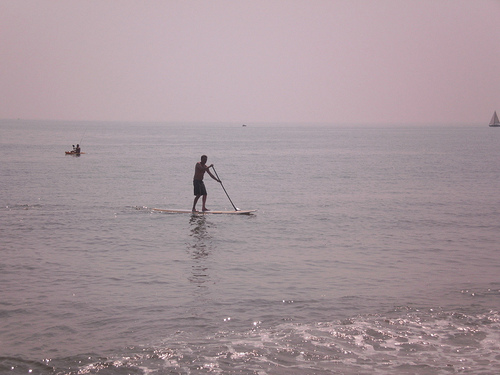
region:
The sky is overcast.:
[1, 8, 498, 124]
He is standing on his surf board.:
[162, 155, 243, 225]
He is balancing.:
[147, 153, 254, 223]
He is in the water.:
[148, 153, 268, 228]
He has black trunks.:
[133, 145, 258, 227]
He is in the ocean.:
[24, 108, 476, 373]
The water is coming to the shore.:
[67, 294, 487, 374]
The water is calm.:
[5, 113, 474, 374]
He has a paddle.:
[146, 143, 251, 220]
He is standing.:
[133, 135, 253, 227]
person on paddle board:
[146, 138, 258, 243]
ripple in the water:
[278, 330, 288, 342]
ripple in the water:
[328, 351, 350, 368]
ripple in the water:
[413, 307, 435, 323]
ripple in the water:
[168, 330, 178, 345]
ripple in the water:
[137, 323, 147, 334]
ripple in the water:
[286, 296, 300, 306]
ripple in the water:
[303, 343, 323, 355]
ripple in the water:
[436, 347, 459, 361]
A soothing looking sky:
[3, 0, 495, 126]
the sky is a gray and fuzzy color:
[0, 3, 495, 122]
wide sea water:
[7, 118, 499, 373]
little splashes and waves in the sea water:
[20, 315, 490, 374]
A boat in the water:
[486, 108, 499, 134]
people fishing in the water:
[63, 133, 88, 156]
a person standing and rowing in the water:
[146, 153, 259, 215]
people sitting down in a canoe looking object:
[60, 141, 85, 156]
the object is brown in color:
[144, 204, 256, 216]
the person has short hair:
[190, 155, 218, 213]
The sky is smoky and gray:
[50, 30, 397, 103]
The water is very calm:
[13, 227, 427, 349]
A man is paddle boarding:
[107, 140, 285, 245]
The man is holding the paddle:
[206, 158, 246, 217]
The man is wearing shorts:
[186, 175, 208, 197]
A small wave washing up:
[126, 303, 472, 368]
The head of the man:
[194, 151, 213, 168]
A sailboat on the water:
[484, 106, 499, 140]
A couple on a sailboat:
[55, 128, 96, 162]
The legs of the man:
[189, 187, 215, 219]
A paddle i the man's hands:
[208, 162, 240, 209]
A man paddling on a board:
[156, 156, 251, 213]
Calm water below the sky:
[0, 117, 499, 369]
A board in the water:
[156, 207, 256, 212]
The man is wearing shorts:
[191, 178, 208, 194]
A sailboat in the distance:
[489, 110, 498, 126]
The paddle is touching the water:
[211, 162, 239, 209]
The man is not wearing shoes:
[187, 206, 209, 211]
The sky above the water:
[1, 2, 498, 125]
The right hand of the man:
[208, 161, 215, 167]